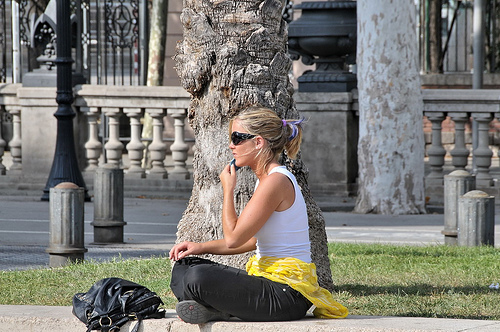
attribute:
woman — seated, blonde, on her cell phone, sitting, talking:
[166, 105, 352, 323]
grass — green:
[1, 239, 499, 319]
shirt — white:
[254, 165, 314, 266]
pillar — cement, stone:
[5, 105, 23, 172]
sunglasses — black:
[231, 131, 257, 146]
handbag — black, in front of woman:
[72, 277, 166, 330]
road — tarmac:
[0, 199, 499, 268]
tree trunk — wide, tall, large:
[173, 0, 335, 294]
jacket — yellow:
[247, 252, 348, 319]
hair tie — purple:
[282, 115, 305, 140]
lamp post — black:
[40, 1, 93, 204]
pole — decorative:
[43, 0, 94, 204]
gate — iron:
[79, 0, 149, 87]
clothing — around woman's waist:
[244, 252, 350, 319]